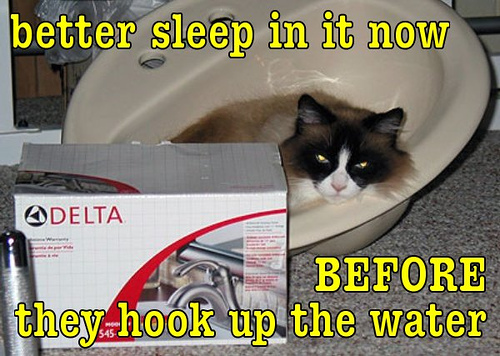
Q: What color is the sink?
A: White.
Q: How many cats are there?
A: One.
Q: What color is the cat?
A: Black, brown, and white.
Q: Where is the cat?
A: In the sink.